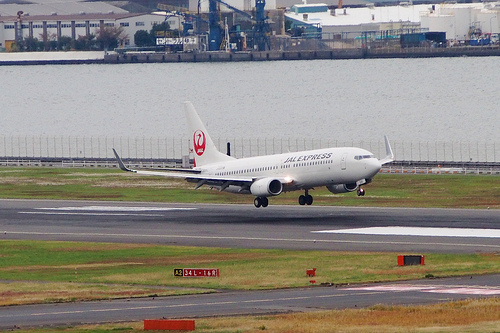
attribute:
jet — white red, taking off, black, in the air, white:
[107, 98, 398, 215]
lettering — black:
[282, 148, 335, 164]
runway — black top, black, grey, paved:
[4, 185, 498, 256]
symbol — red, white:
[190, 130, 209, 156]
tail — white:
[178, 97, 225, 168]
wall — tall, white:
[1, 53, 499, 179]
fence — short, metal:
[1, 130, 500, 176]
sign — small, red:
[183, 265, 221, 278]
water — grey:
[1, 59, 499, 169]